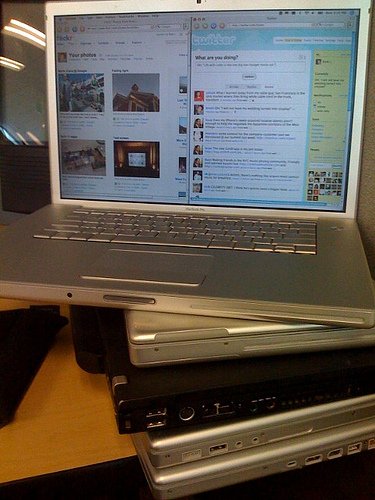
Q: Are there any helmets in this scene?
A: No, there are no helmets.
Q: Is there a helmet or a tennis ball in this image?
A: No, there are no helmets or tennis balls.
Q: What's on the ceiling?
A: The ceiling light is on the ceiling.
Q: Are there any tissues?
A: No, there are no tissues.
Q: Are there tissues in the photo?
A: No, there are no tissues.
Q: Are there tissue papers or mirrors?
A: No, there are no tissue papers or mirrors.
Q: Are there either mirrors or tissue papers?
A: No, there are no tissue papers or mirrors.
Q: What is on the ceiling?
A: The ceiling light is on the ceiling.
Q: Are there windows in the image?
A: Yes, there is a window.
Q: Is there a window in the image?
A: Yes, there is a window.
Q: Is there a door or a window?
A: Yes, there is a window.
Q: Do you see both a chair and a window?
A: No, there is a window but no chairs.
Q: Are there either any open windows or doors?
A: Yes, there is an open window.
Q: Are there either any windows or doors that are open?
A: Yes, the window is open.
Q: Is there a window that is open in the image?
A: Yes, there is an open window.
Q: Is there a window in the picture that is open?
A: Yes, there is a window that is open.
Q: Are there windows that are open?
A: Yes, there is a window that is open.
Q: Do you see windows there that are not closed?
A: Yes, there is a open window.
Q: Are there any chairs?
A: No, there are no chairs.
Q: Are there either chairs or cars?
A: No, there are no chairs or cars.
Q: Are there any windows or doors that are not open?
A: No, there is a window but it is open.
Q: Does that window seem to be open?
A: Yes, the window is open.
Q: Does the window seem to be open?
A: Yes, the window is open.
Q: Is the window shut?
A: No, the window is open.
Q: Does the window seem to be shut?
A: No, the window is open.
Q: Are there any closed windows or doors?
A: No, there is a window but it is open.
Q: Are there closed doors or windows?
A: No, there is a window but it is open.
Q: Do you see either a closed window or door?
A: No, there is a window but it is open.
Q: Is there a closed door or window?
A: No, there is a window but it is open.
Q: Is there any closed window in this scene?
A: No, there is a window but it is open.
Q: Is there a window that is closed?
A: No, there is a window but it is open.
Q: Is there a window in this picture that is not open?
A: No, there is a window but it is open.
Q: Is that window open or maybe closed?
A: The window is open.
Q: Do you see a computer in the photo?
A: Yes, there is a computer.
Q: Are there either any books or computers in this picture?
A: Yes, there is a computer.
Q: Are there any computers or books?
A: Yes, there is a computer.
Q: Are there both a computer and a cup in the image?
A: No, there is a computer but no cups.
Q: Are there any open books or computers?
A: Yes, there is an open computer.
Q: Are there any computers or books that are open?
A: Yes, the computer is open.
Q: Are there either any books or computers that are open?
A: Yes, the computer is open.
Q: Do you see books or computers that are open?
A: Yes, the computer is open.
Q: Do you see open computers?
A: Yes, there is an open computer.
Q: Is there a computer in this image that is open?
A: Yes, there is a computer that is open.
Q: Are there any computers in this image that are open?
A: Yes, there is a computer that is open.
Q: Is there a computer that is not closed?
A: Yes, there is a open computer.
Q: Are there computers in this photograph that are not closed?
A: Yes, there is a open computer.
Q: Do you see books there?
A: No, there are no books.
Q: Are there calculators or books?
A: No, there are no books or calculators.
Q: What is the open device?
A: The device is a computer.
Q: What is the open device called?
A: The device is a computer.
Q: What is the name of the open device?
A: The device is a computer.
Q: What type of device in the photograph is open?
A: The device is a computer.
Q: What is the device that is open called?
A: The device is a computer.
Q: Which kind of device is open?
A: The device is a computer.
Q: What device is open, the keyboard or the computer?
A: The computer is open.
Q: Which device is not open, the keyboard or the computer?
A: The keyboard is not open.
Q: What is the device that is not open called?
A: The device is a keyboard.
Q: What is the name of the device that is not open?
A: The device is a keyboard.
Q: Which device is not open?
A: The device is a keyboard.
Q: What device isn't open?
A: The device is a keyboard.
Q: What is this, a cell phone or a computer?
A: This is a computer.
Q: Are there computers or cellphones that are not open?
A: No, there is a computer but it is open.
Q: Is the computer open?
A: Yes, the computer is open.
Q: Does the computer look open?
A: Yes, the computer is open.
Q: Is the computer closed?
A: No, the computer is open.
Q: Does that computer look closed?
A: No, the computer is open.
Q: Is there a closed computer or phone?
A: No, there is a computer but it is open.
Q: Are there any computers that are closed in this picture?
A: No, there is a computer but it is open.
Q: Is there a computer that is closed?
A: No, there is a computer but it is open.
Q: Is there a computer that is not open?
A: No, there is a computer but it is open.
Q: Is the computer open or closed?
A: The computer is open.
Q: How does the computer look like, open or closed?
A: The computer is open.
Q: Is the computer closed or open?
A: The computer is open.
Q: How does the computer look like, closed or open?
A: The computer is open.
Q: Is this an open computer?
A: Yes, this is an open computer.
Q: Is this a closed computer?
A: No, this is an open computer.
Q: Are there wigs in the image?
A: No, there are no wigs.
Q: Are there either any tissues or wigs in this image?
A: No, there are no wigs or tissues.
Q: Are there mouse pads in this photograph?
A: Yes, there is a mouse pad.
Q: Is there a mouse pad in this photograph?
A: Yes, there is a mouse pad.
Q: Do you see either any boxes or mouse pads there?
A: Yes, there is a mouse pad.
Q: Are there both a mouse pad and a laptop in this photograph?
A: Yes, there are both a mouse pad and a laptop.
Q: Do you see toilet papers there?
A: No, there are no toilet papers.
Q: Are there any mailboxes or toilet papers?
A: No, there are no toilet papers or mailboxes.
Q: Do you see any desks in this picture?
A: Yes, there is a desk.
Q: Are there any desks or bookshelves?
A: Yes, there is a desk.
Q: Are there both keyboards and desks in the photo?
A: Yes, there are both a desk and a keyboard.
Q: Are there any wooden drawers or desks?
A: Yes, there is a wood desk.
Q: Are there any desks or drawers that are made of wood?
A: Yes, the desk is made of wood.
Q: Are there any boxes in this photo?
A: No, there are no boxes.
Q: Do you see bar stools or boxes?
A: No, there are no boxes or bar stools.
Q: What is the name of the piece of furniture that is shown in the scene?
A: The piece of furniture is a desk.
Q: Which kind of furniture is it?
A: The piece of furniture is a desk.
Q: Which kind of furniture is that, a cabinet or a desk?
A: That is a desk.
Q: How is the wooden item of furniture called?
A: The piece of furniture is a desk.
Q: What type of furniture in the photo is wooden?
A: The furniture is a desk.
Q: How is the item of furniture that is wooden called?
A: The piece of furniture is a desk.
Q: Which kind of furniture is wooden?
A: The furniture is a desk.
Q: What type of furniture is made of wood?
A: The furniture is a desk.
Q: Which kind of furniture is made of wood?
A: The furniture is a desk.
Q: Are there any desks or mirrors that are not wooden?
A: No, there is a desk but it is wooden.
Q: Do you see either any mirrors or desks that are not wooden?
A: No, there is a desk but it is wooden.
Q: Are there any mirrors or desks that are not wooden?
A: No, there is a desk but it is wooden.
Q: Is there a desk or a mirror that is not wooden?
A: No, there is a desk but it is wooden.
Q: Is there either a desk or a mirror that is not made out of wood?
A: No, there is a desk but it is made of wood.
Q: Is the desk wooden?
A: Yes, the desk is wooden.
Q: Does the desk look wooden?
A: Yes, the desk is wooden.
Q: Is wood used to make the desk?
A: Yes, the desk is made of wood.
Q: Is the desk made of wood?
A: Yes, the desk is made of wood.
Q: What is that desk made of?
A: The desk is made of wood.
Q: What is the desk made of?
A: The desk is made of wood.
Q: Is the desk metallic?
A: No, the desk is wooden.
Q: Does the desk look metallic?
A: No, the desk is wooden.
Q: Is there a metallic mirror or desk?
A: No, there is a desk but it is wooden.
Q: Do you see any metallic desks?
A: No, there is a desk but it is wooden.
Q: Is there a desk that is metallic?
A: No, there is a desk but it is wooden.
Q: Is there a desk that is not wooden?
A: No, there is a desk but it is wooden.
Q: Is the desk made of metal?
A: No, the desk is made of wood.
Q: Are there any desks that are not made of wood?
A: No, there is a desk but it is made of wood.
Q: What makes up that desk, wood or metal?
A: The desk is made of wood.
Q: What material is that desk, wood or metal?
A: The desk is made of wood.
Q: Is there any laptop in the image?
A: Yes, there is a laptop.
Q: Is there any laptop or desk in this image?
A: Yes, there is a laptop.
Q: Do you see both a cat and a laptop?
A: No, there is a laptop but no cats.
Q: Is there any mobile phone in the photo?
A: No, there are no cell phones.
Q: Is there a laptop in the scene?
A: Yes, there is a laptop.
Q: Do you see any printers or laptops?
A: Yes, there is a laptop.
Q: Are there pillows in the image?
A: No, there are no pillows.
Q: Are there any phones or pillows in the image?
A: No, there are no pillows or phones.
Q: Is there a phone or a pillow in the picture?
A: No, there are no pillows or phones.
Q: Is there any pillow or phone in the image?
A: No, there are no pillows or phones.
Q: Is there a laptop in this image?
A: Yes, there is a laptop.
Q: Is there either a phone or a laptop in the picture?
A: Yes, there is a laptop.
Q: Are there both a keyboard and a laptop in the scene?
A: Yes, there are both a laptop and a keyboard.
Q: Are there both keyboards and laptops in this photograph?
A: Yes, there are both a laptop and a keyboard.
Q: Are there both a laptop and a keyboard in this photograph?
A: Yes, there are both a laptop and a keyboard.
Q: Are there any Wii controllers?
A: No, there are no Wii controllers.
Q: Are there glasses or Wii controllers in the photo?
A: No, there are no Wii controllers or glasses.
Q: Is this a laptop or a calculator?
A: This is a laptop.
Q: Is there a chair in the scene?
A: No, there are no chairs.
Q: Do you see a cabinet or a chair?
A: No, there are no chairs or cabinets.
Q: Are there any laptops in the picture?
A: Yes, there is a laptop.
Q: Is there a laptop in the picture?
A: Yes, there is a laptop.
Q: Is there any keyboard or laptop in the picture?
A: Yes, there is a laptop.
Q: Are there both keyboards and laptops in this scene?
A: Yes, there are both a laptop and a keyboard.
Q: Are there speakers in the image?
A: No, there are no speakers.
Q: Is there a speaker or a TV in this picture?
A: No, there are no speakers or televisions.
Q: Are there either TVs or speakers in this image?
A: No, there are no speakers or tvs.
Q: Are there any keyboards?
A: Yes, there is a keyboard.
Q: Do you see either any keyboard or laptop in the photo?
A: Yes, there is a keyboard.